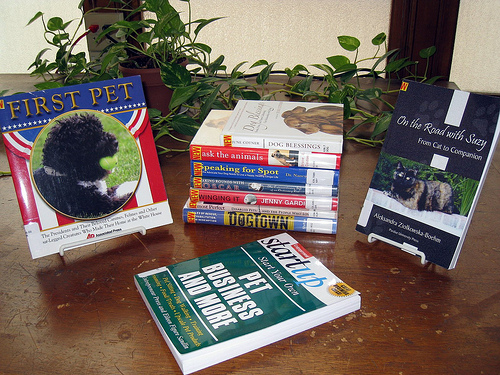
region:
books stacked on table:
[183, 98, 345, 229]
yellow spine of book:
[222, 208, 286, 228]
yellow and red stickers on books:
[181, 143, 206, 226]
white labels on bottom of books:
[297, 155, 335, 242]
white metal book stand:
[361, 231, 426, 268]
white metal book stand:
[58, 225, 146, 262]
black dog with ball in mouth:
[41, 109, 115, 207]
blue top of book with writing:
[0, 83, 137, 120]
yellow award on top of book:
[329, 274, 357, 300]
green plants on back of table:
[124, 23, 374, 113]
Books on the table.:
[151, 103, 365, 270]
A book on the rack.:
[355, 86, 476, 281]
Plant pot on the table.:
[108, 5, 230, 112]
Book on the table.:
[151, 253, 359, 332]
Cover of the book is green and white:
[175, 249, 280, 330]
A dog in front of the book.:
[25, 108, 140, 207]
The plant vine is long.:
[135, 25, 397, 114]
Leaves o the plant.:
[129, 25, 409, 108]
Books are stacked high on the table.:
[170, 104, 366, 241]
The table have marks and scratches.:
[340, 260, 491, 356]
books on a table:
[11, 12, 483, 350]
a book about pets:
[4, 79, 162, 258]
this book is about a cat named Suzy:
[369, 71, 493, 286]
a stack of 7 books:
[178, 88, 353, 235]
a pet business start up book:
[149, 205, 360, 362]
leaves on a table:
[94, 28, 383, 108]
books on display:
[9, 59, 479, 346]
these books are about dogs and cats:
[7, 67, 476, 355]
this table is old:
[24, 263, 412, 373]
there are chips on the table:
[317, 262, 459, 362]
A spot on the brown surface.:
[111, 327, 134, 344]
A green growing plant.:
[0, 0, 472, 155]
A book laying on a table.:
[133, 229, 363, 373]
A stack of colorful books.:
[181, 98, 345, 238]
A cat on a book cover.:
[383, 159, 460, 212]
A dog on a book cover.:
[29, 112, 143, 219]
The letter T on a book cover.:
[116, 80, 136, 101]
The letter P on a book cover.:
[86, 85, 102, 106]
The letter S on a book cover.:
[48, 90, 68, 111]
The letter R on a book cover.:
[31, 94, 51, 115]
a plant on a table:
[18, 5, 423, 112]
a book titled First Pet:
[2, 74, 137, 118]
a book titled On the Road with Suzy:
[395, 109, 491, 152]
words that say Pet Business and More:
[174, 254, 274, 333]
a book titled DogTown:
[224, 208, 294, 231]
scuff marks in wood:
[20, 270, 140, 366]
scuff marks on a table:
[13, 260, 139, 356]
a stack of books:
[177, 88, 344, 236]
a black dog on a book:
[23, 108, 144, 222]